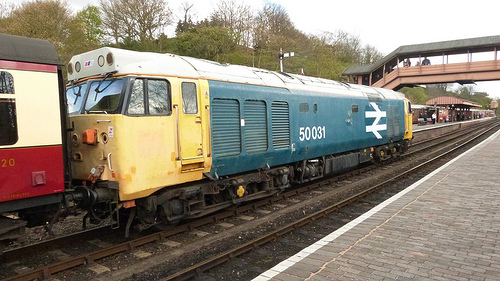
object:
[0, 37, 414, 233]
train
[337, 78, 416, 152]
engine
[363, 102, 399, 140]
company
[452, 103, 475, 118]
passengers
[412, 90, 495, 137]
depot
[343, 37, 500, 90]
bridge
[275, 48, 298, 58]
lights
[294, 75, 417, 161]
rear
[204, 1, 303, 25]
tree tops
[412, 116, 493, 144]
brick walkway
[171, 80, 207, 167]
door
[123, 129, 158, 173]
yellow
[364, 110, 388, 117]
white lines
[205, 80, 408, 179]
blue background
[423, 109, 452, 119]
people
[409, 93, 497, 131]
platform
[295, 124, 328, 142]
numbers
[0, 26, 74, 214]
caboose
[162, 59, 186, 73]
white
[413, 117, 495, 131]
white stripe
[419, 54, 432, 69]
pedestrian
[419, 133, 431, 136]
brick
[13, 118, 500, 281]
railroad